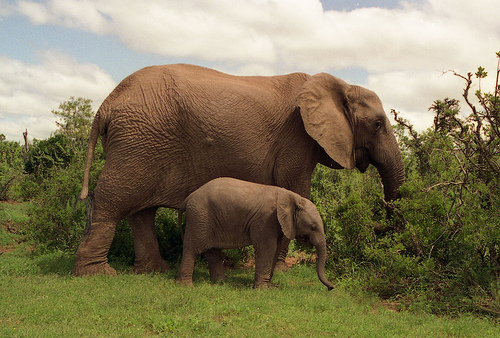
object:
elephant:
[178, 177, 328, 295]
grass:
[2, 196, 499, 338]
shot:
[4, 1, 498, 338]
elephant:
[72, 63, 404, 275]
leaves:
[424, 225, 439, 244]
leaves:
[379, 236, 395, 250]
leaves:
[361, 245, 381, 261]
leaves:
[384, 250, 401, 268]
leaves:
[402, 255, 421, 273]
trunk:
[317, 246, 333, 293]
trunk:
[374, 138, 409, 217]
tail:
[80, 107, 100, 200]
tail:
[177, 198, 188, 241]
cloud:
[21, 2, 500, 68]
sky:
[0, 0, 497, 145]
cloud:
[0, 54, 118, 142]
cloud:
[367, 68, 499, 140]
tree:
[19, 97, 110, 268]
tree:
[305, 164, 384, 267]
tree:
[410, 62, 497, 313]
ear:
[276, 191, 295, 240]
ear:
[294, 72, 360, 169]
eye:
[309, 225, 316, 231]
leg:
[205, 247, 229, 284]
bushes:
[367, 137, 450, 270]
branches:
[459, 67, 483, 158]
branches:
[476, 86, 500, 146]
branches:
[422, 173, 468, 193]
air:
[389, 21, 495, 218]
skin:
[85, 76, 340, 277]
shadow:
[170, 266, 275, 286]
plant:
[0, 127, 52, 201]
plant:
[317, 171, 372, 238]